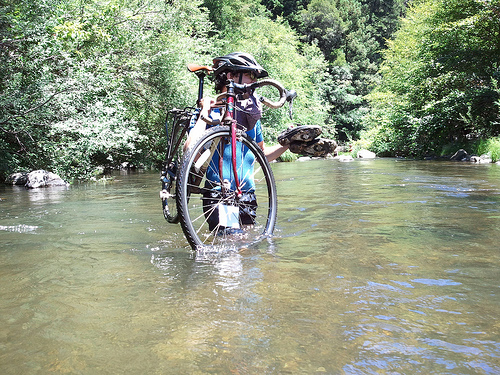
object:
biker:
[183, 52, 295, 241]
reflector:
[194, 148, 211, 173]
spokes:
[187, 136, 271, 247]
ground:
[371, 160, 409, 195]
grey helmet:
[212, 51, 269, 93]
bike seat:
[187, 63, 213, 74]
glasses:
[245, 73, 255, 79]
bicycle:
[158, 62, 298, 257]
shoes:
[277, 125, 323, 152]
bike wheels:
[175, 126, 278, 256]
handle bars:
[234, 83, 298, 120]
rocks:
[4, 169, 70, 189]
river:
[0, 156, 499, 374]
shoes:
[289, 138, 338, 157]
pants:
[203, 180, 258, 236]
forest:
[0, 0, 499, 181]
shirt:
[188, 98, 265, 193]